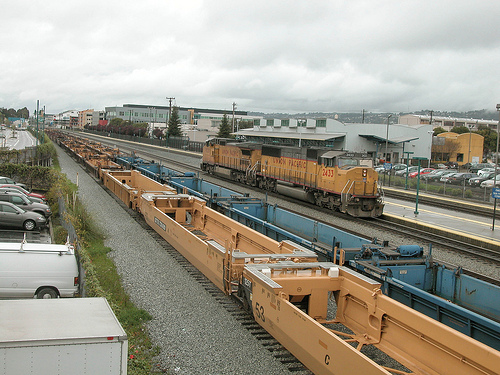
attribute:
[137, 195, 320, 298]
container car — yellow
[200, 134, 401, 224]
locomotive — double engine, moving, yellow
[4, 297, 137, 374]
trailer — white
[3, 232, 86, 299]
van — parked, white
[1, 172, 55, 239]
cars — parked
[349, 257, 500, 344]
train car — blue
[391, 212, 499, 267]
tracks — empty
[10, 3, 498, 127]
sky — cloudy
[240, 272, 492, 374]
train — unconstructed, yellow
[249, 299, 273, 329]
53 — painted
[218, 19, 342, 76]
clouds — gray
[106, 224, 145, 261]
gravel — gray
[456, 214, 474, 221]
line — yellow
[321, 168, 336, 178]
number — red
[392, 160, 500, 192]
cars — parked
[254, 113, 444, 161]
building — white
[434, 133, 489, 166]
business — yellow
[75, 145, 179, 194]
train car — yellow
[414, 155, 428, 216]
post — green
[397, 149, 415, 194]
post — green